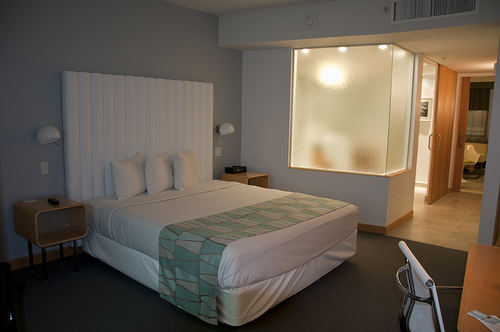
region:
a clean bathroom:
[7, 5, 497, 325]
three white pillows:
[102, 143, 213, 208]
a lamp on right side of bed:
[207, 115, 244, 143]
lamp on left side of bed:
[28, 117, 67, 154]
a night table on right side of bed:
[222, 157, 276, 187]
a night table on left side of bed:
[9, 187, 95, 267]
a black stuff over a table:
[216, 158, 254, 177]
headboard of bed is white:
[56, 62, 225, 203]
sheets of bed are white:
[82, 170, 367, 312]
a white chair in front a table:
[379, 239, 450, 329]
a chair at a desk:
[390, 232, 447, 329]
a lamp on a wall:
[34, 117, 64, 152]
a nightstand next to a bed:
[12, 182, 97, 268]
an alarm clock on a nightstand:
[221, 155, 249, 175]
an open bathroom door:
[413, 59, 445, 217]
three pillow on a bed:
[114, 138, 202, 205]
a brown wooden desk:
[449, 235, 499, 329]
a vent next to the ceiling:
[388, 2, 483, 19]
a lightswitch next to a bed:
[39, 156, 53, 177]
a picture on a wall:
[416, 92, 433, 127]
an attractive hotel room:
[17, 8, 489, 325]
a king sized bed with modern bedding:
[55, 65, 369, 317]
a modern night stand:
[11, 184, 115, 263]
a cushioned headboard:
[48, 59, 219, 196]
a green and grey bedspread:
[153, 217, 247, 322]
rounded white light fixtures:
[31, 117, 61, 154]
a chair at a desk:
[383, 216, 497, 331]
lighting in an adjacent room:
[284, 14, 421, 93]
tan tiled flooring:
[423, 208, 475, 245]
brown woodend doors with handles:
[421, 41, 473, 208]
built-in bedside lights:
[31, 122, 63, 150]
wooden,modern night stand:
[13, 190, 94, 279]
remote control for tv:
[46, 192, 61, 207]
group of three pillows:
[96, 157, 206, 197]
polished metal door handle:
[432, 127, 442, 152]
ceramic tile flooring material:
[420, 196, 473, 232]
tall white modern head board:
[65, 71, 216, 188]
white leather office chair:
[395, 235, 456, 328]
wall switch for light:
[37, 158, 49, 174]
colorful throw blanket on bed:
[163, 210, 278, 256]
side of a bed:
[145, 231, 147, 256]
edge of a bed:
[275, 264, 292, 285]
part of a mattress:
[235, 197, 268, 215]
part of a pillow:
[150, 178, 162, 182]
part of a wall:
[262, 147, 268, 167]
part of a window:
[385, 102, 414, 126]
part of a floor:
[71, 260, 76, 274]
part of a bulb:
[48, 137, 59, 169]